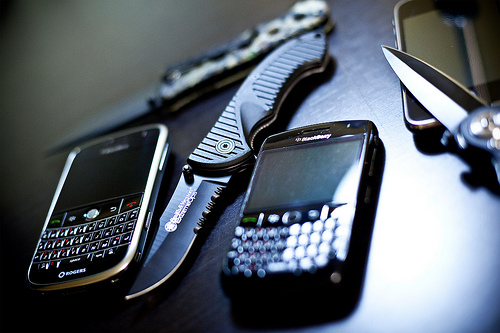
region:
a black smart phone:
[222, 117, 400, 313]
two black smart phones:
[28, 107, 389, 313]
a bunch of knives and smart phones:
[18, 10, 489, 295]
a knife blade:
[115, 161, 240, 304]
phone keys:
[209, 214, 374, 303]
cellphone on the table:
[30, 124, 170, 281]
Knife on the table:
[113, 28, 333, 301]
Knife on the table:
[362, 25, 498, 168]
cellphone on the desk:
[238, 98, 366, 313]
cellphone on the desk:
[25, 115, 170, 290]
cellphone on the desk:
[384, 2, 498, 152]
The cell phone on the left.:
[26, 120, 171, 286]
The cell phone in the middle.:
[220, 120, 376, 295]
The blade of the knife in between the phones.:
[125, 170, 230, 291]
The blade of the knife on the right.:
[380, 40, 475, 125]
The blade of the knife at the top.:
[40, 90, 165, 145]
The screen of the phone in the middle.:
[250, 140, 360, 206]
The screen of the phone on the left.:
[51, 151, 151, 211]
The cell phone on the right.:
[390, 1, 497, 127]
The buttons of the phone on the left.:
[36, 215, 136, 260]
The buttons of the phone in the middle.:
[223, 219, 349, 269]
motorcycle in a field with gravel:
[331, 290, 348, 302]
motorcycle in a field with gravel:
[353, 268, 367, 279]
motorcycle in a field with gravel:
[341, 298, 349, 308]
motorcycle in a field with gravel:
[346, 277, 381, 301]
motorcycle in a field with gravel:
[371, 261, 393, 278]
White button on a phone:
[37, 230, 56, 242]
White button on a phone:
[58, 224, 80, 240]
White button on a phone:
[78, 221, 100, 233]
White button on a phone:
[97, 214, 118, 236]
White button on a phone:
[114, 213, 140, 234]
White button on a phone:
[35, 237, 58, 259]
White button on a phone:
[53, 231, 77, 252]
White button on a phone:
[78, 228, 97, 248]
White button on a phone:
[88, 230, 120, 252]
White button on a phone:
[110, 218, 135, 240]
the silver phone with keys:
[24, 120, 171, 287]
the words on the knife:
[164, 185, 196, 232]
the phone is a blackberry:
[221, 120, 371, 288]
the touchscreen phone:
[393, 3, 498, 135]